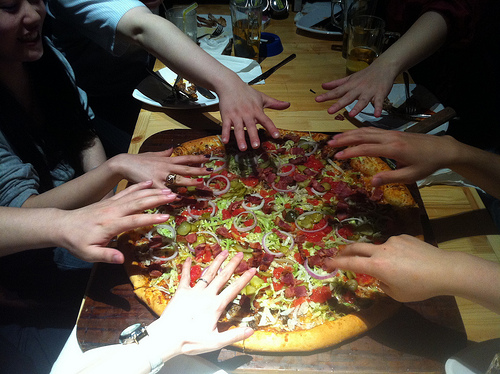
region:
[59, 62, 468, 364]
LOTS OF HANDS REACHING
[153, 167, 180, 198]
THE GIRL IS WEARING A RING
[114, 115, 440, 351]
THE PIZZA HAS LOTS OF TOPPINGS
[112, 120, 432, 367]
THE PIZZA IS ROUND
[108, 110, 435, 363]
THE PIZZA IS SLICED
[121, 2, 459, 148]
THE PLATES ARE WHITE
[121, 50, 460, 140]
THE SILVERWARE IS ON THE PLATES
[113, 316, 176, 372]
THE GIRL IS WEARING A WATCH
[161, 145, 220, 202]
THE GIRLS FINGERNAILS ARE PAINTED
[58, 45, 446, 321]
seven hands over a pizza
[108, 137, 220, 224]
ring on woman's hand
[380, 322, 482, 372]
brown wooden serving tray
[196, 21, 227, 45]
silver fork on a napkin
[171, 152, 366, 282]
large pizza with all the trimmings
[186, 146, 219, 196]
red and black nail polish on nails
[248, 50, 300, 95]
kitchen knife on napkin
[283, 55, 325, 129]
light colored wooden dining table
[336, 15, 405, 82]
glass of beer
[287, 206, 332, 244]
red onion on pizza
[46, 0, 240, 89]
the arm of a person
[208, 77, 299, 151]
the hand of a person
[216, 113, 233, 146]
the finger of a person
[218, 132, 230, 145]
the finger nail of a person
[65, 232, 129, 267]
the thumb of a person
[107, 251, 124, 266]
the thumb nail of a person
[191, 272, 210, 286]
a ring on the finger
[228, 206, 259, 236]
a ring of onion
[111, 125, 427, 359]
a pizza on the cutting board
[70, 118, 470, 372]
a brown wooden cutting board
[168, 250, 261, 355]
Hand of restaurant customer.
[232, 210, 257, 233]
Onion on pizza.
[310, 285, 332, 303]
tomatoe on pizza.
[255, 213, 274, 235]
lettuce on pizza.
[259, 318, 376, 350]
pizza crust.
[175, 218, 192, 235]
pickel on pizza.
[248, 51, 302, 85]
black knife on restaurant table.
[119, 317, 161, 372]
white watch on restaurant customers hand.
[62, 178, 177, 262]
Hand on the side of restaurant table.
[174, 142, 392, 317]
Supreme pizza on restaurant table.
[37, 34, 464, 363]
seven hands over top of a pizza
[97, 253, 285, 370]
the hand wearing a watch and a ring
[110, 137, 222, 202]
hand with black and red nail polish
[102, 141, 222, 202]
hand with a large ring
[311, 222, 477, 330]
hand that is pointing with two fingers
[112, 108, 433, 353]
a pizza with many toppings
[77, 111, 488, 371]
brown wooden pizza tray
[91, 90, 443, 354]
a pizza with a golden crust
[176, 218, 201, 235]
green dill pickles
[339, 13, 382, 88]
a glass of beer